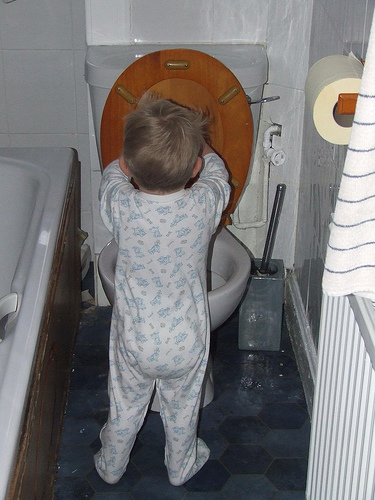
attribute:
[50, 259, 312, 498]
floor — blue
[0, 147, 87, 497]
bath tub — white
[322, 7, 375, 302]
cloth — hanging, striped, blue, white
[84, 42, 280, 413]
toilet — white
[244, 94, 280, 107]
handle — metal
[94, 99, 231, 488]
baby — standing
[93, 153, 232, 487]
pajamas — blue, white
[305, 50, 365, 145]
toilet paper — yellowish, rolled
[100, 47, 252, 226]
toilet seat — wooden, open, brown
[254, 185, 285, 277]
toilet brush — metal, silver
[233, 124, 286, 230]
pipe — white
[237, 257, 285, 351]
box — metal